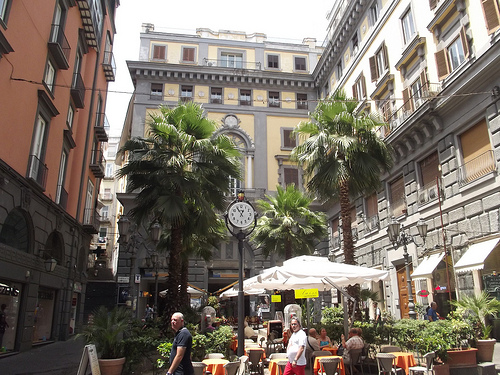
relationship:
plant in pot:
[71, 307, 141, 356] [93, 356, 126, 373]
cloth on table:
[390, 352, 420, 374] [382, 349, 415, 359]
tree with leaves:
[110, 93, 259, 315] [183, 134, 243, 185]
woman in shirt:
[281, 313, 316, 373] [287, 331, 309, 363]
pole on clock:
[228, 226, 249, 371] [222, 199, 257, 226]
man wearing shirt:
[279, 314, 309, 374] [286, 329, 307, 366]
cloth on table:
[396, 351, 415, 366] [378, 342, 425, 371]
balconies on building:
[78, 59, 149, 269] [2, 0, 119, 355]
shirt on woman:
[284, 326, 310, 367] [282, 315, 312, 373]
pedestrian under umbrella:
[160, 302, 440, 375] [219, 254, 390, 299]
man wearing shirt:
[166, 316, 218, 368] [172, 330, 213, 372]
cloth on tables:
[390, 352, 420, 374] [204, 316, 425, 373]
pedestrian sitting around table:
[160, 302, 440, 375] [321, 341, 335, 352]